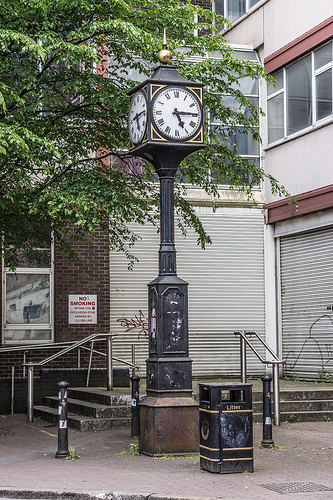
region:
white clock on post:
[152, 85, 202, 142]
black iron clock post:
[129, 143, 202, 456]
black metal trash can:
[198, 382, 254, 473]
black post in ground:
[56, 380, 68, 457]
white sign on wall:
[69, 294, 97, 323]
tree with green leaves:
[1, 1, 250, 267]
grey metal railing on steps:
[21, 331, 113, 422]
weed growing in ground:
[67, 444, 80, 460]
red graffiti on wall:
[115, 311, 148, 339]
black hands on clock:
[172, 109, 196, 128]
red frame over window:
[262, 19, 330, 146]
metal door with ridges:
[278, 225, 331, 380]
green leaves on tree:
[0, 7, 280, 269]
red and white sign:
[68, 293, 96, 324]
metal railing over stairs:
[233, 328, 286, 423]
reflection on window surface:
[7, 272, 50, 341]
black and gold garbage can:
[200, 381, 253, 472]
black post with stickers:
[54, 381, 69, 459]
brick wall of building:
[2, 207, 109, 376]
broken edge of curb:
[0, 489, 179, 499]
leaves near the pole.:
[69, 444, 79, 461]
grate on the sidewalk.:
[279, 481, 318, 494]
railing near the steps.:
[246, 336, 268, 361]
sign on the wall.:
[68, 296, 95, 321]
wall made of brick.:
[60, 274, 74, 284]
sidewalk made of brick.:
[119, 469, 168, 488]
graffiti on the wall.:
[303, 319, 332, 353]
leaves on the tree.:
[68, 186, 100, 209]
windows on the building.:
[270, 102, 308, 120]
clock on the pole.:
[140, 91, 197, 149]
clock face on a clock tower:
[154, 88, 201, 142]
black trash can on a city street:
[193, 376, 258, 483]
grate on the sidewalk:
[256, 479, 330, 497]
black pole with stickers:
[49, 376, 71, 464]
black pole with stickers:
[127, 377, 144, 442]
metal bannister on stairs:
[230, 323, 290, 431]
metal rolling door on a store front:
[198, 258, 229, 332]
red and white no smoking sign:
[54, 275, 113, 340]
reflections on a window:
[8, 271, 56, 338]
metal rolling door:
[285, 248, 316, 319]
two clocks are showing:
[92, 42, 214, 154]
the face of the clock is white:
[127, 64, 221, 161]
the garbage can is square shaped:
[156, 365, 266, 478]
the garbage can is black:
[189, 374, 262, 481]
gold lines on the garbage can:
[183, 431, 261, 473]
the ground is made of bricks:
[68, 451, 180, 494]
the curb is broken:
[69, 481, 146, 498]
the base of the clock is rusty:
[115, 388, 198, 458]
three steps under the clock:
[248, 370, 322, 428]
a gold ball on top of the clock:
[145, 42, 182, 71]